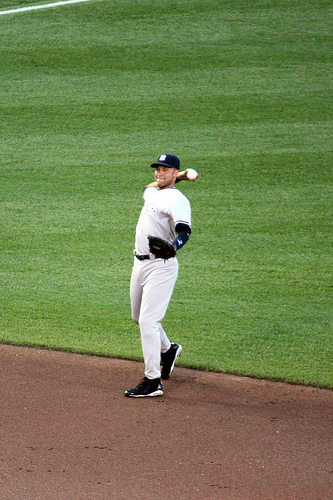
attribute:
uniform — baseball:
[128, 184, 193, 382]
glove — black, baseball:
[146, 230, 204, 273]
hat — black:
[146, 148, 184, 169]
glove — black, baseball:
[146, 235, 175, 259]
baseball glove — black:
[88, 130, 204, 246]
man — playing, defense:
[121, 153, 226, 390]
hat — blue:
[146, 153, 180, 172]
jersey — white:
[126, 182, 213, 257]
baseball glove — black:
[145, 236, 177, 259]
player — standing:
[120, 150, 192, 400]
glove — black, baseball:
[141, 234, 183, 265]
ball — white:
[186, 169, 198, 178]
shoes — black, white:
[123, 342, 180, 398]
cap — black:
[147, 149, 183, 173]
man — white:
[85, 139, 234, 465]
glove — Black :
[146, 232, 175, 261]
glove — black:
[145, 230, 179, 260]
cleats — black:
[122, 339, 185, 398]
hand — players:
[148, 236, 178, 259]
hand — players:
[144, 235, 179, 261]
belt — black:
[135, 247, 168, 263]